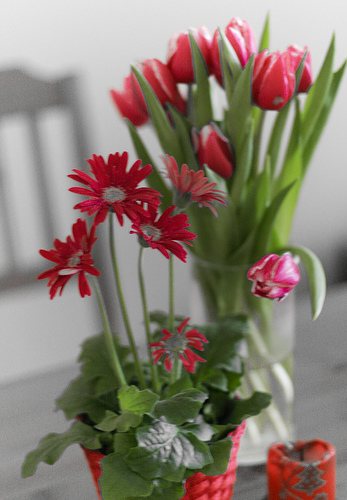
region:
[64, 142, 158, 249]
flower with many petals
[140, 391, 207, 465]
leaves on the plant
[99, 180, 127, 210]
middle part of flower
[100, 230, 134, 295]
stem of the flower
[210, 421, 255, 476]
red basket holding flowers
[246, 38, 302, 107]
closed red plant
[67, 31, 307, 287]
two plants next to each other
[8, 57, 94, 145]
blurry background of photo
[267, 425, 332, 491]
item next to plant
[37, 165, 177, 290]
three flowers next to each other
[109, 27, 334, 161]
these are the flowers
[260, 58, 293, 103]
the flower is red in color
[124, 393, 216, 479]
the leaves are green in color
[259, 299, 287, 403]
this is a glass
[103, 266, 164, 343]
the stem are thin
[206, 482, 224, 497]
the cup is red in color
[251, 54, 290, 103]
the flower is fresh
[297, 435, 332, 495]
this is a candle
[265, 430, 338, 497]
the candle is off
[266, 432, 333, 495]
the candle is small in size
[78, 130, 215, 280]
A flower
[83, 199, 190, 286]
A flower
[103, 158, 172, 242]
A flower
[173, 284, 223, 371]
A flower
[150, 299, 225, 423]
A flower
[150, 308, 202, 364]
A flower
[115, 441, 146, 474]
edge of a eaf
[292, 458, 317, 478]
edge a candle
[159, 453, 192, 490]
edge of a leaf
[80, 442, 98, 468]
edge of a vase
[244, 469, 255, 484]
part of a surface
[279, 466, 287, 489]
part of a a candle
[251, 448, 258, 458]
part of a chair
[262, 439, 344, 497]
RED CANDLE TO RIGHT OF PLANT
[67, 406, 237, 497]
PLANT IS IN RED BASKET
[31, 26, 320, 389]
TWO DIFFERENT KINDS OF FLOWERS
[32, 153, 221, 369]
FIVE GERBER DAISIES IN THE PLANT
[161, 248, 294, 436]
CUT FLOWERS IN A VASE OF WATER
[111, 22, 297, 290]
TULIPS ARE IN THE VASE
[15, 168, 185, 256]
GERBER DAISIES ARE RED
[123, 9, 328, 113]
TULIPS ARE OF A RED COLOR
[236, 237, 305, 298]
THE SINGLE TULIP IS RED AND WHITE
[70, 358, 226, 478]
THE DAISY LEAVES ARE GREEN